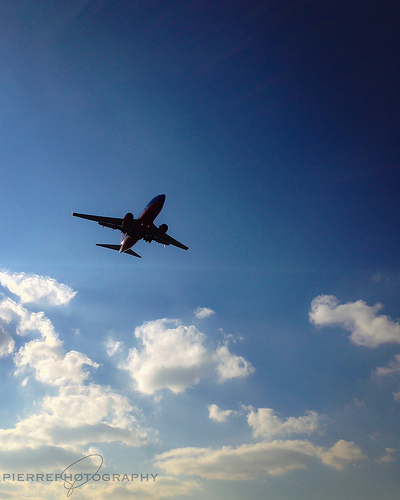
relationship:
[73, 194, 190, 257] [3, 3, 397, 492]
airplane in sky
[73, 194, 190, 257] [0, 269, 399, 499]
airplane amidst clouds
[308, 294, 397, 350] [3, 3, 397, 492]
cloud in sky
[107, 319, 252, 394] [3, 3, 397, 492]
cloud in sky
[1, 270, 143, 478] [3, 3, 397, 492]
cloud in sky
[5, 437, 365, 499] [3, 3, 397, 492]
cloud in sky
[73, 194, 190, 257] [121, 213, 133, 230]
airplane has engine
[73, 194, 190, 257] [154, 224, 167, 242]
airplane has engine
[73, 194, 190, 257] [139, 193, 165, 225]
airplane has nose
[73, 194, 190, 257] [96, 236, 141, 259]
airplane has a tail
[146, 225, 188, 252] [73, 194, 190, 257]
wing on an airplane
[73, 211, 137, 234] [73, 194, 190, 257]
wing on an airplane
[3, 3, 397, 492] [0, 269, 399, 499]
sky has clouds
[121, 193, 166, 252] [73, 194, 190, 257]
body of airplane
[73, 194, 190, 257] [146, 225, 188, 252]
airplane has wing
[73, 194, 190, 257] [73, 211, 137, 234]
airplane has wing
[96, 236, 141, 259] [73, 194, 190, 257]
tail of airplane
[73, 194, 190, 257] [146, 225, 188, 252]
airplane has right wing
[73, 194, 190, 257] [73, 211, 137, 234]
airplane has left wing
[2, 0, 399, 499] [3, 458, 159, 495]
photo has logo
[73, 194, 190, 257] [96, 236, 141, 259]
airplane has tail